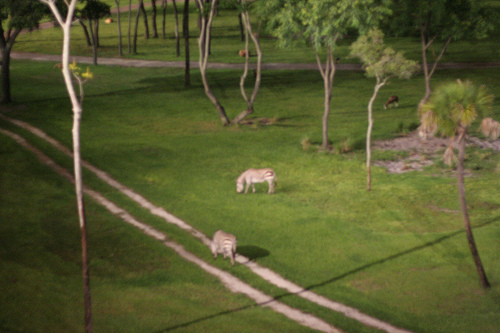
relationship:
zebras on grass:
[197, 159, 277, 263] [8, 2, 498, 332]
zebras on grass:
[206, 230, 237, 263] [8, 2, 498, 332]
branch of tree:
[430, 34, 464, 77] [408, 6, 492, 109]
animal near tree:
[382, 90, 400, 112] [408, 6, 492, 109]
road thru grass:
[6, 46, 499, 87] [8, 2, 498, 332]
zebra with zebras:
[238, 162, 277, 196] [206, 230, 237, 263]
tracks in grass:
[5, 114, 411, 329] [8, 2, 498, 332]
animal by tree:
[382, 90, 400, 112] [408, 6, 492, 109]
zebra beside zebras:
[238, 162, 277, 196] [206, 230, 237, 263]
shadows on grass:
[34, 62, 347, 103] [8, 2, 498, 332]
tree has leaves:
[408, 6, 492, 109] [396, 3, 489, 39]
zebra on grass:
[238, 162, 277, 196] [8, 2, 498, 332]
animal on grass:
[382, 90, 400, 112] [8, 2, 498, 332]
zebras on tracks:
[206, 230, 237, 263] [5, 114, 411, 329]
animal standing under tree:
[382, 90, 400, 112] [408, 6, 492, 109]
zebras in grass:
[197, 159, 277, 263] [8, 2, 498, 332]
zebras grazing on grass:
[197, 159, 277, 263] [8, 2, 498, 332]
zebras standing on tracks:
[206, 230, 237, 263] [5, 114, 411, 329]